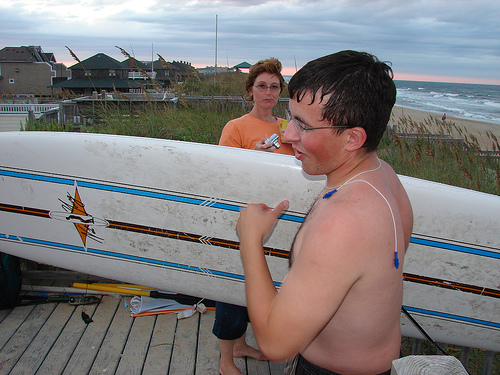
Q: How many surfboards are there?
A: One.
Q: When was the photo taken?
A: Daytime.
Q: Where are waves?
A: In the ocean.